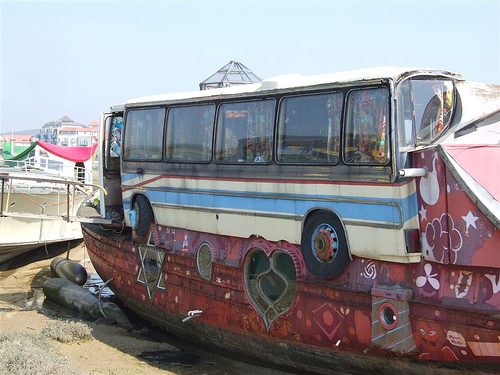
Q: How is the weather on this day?
A: It is clear.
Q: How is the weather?
A: It is clear.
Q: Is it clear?
A: Yes, it is clear.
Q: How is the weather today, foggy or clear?
A: It is clear.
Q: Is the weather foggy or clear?
A: It is clear.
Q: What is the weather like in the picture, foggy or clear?
A: It is clear.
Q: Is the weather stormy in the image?
A: No, it is clear.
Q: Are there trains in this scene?
A: No, there are no trains.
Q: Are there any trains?
A: No, there are no trains.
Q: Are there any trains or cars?
A: No, there are no trains or cars.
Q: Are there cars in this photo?
A: No, there are no cars.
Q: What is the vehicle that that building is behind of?
A: The vehicle is a bus.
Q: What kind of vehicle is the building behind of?
A: The building is behind the bus.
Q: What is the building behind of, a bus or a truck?
A: The building is behind a bus.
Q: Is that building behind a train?
A: No, the building is behind the bus.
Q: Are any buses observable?
A: Yes, there is a bus.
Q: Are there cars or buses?
A: Yes, there is a bus.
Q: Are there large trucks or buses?
A: Yes, there is a large bus.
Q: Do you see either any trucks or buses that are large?
A: Yes, the bus is large.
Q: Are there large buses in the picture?
A: Yes, there is a large bus.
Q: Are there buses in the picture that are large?
A: Yes, there is a bus that is large.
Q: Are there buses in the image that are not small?
A: Yes, there is a large bus.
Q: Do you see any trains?
A: No, there are no trains.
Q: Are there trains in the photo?
A: No, there are no trains.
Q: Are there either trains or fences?
A: No, there are no trains or fences.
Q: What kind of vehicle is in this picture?
A: The vehicle is a bus.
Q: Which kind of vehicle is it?
A: The vehicle is a bus.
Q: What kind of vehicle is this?
A: This is a bus.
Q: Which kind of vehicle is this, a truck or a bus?
A: This is a bus.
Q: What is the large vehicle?
A: The vehicle is a bus.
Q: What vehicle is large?
A: The vehicle is a bus.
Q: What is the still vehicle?
A: The vehicle is a bus.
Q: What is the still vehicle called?
A: The vehicle is a bus.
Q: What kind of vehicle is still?
A: The vehicle is a bus.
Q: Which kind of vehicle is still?
A: The vehicle is a bus.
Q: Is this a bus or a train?
A: This is a bus.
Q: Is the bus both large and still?
A: Yes, the bus is large and still.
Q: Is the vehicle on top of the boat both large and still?
A: Yes, the bus is large and still.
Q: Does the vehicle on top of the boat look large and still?
A: Yes, the bus is large and still.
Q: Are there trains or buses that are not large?
A: No, there is a bus but it is large.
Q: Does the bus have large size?
A: Yes, the bus is large.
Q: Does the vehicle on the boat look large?
A: Yes, the bus is large.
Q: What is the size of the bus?
A: The bus is large.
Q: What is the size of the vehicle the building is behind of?
A: The bus is large.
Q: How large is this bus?
A: The bus is large.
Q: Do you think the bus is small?
A: No, the bus is large.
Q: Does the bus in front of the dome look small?
A: No, the bus is large.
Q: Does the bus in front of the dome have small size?
A: No, the bus is large.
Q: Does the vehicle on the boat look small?
A: No, the bus is large.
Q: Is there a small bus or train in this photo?
A: No, there is a bus but it is large.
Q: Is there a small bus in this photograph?
A: No, there is a bus but it is large.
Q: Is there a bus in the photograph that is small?
A: No, there is a bus but it is large.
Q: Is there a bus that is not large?
A: No, there is a bus but it is large.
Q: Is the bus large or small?
A: The bus is large.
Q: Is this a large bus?
A: Yes, this is a large bus.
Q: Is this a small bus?
A: No, this is a large bus.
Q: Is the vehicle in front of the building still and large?
A: Yes, the bus is still and large.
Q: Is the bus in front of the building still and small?
A: No, the bus is still but large.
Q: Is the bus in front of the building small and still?
A: No, the bus is still but large.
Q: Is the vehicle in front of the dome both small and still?
A: No, the bus is still but large.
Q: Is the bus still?
A: Yes, the bus is still.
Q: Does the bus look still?
A: Yes, the bus is still.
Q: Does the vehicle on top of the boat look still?
A: Yes, the bus is still.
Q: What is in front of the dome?
A: The bus is in front of the dome.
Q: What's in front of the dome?
A: The bus is in front of the dome.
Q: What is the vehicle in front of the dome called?
A: The vehicle is a bus.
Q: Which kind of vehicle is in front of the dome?
A: The vehicle is a bus.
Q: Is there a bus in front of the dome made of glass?
A: Yes, there is a bus in front of the dome.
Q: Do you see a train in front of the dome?
A: No, there is a bus in front of the dome.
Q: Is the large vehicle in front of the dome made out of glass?
A: Yes, the bus is in front of the dome.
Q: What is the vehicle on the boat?
A: The vehicle is a bus.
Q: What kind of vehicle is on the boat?
A: The vehicle is a bus.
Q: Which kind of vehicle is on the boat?
A: The vehicle is a bus.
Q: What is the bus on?
A: The bus is on the boat.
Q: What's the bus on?
A: The bus is on the boat.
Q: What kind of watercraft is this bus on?
A: The bus is on the boat.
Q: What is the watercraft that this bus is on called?
A: The watercraft is a boat.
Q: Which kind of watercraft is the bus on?
A: The bus is on the boat.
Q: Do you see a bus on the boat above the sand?
A: Yes, there is a bus on the boat.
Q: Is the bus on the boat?
A: Yes, the bus is on the boat.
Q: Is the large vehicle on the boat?
A: Yes, the bus is on the boat.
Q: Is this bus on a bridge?
A: No, the bus is on the boat.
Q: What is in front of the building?
A: The bus is in front of the building.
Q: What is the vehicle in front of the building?
A: The vehicle is a bus.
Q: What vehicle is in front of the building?
A: The vehicle is a bus.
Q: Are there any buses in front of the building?
A: Yes, there is a bus in front of the building.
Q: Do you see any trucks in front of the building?
A: No, there is a bus in front of the building.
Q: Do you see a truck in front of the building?
A: No, there is a bus in front of the building.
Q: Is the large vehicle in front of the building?
A: Yes, the bus is in front of the building.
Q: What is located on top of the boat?
A: The bus is on top of the boat.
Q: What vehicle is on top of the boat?
A: The vehicle is a bus.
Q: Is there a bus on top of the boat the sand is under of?
A: Yes, there is a bus on top of the boat.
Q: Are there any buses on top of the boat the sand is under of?
A: Yes, there is a bus on top of the boat.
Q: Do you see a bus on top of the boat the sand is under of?
A: Yes, there is a bus on top of the boat.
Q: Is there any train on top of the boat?
A: No, there is a bus on top of the boat.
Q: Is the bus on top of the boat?
A: Yes, the bus is on top of the boat.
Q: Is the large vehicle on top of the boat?
A: Yes, the bus is on top of the boat.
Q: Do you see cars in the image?
A: No, there are no cars.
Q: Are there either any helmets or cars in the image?
A: No, there are no cars or helmets.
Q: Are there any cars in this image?
A: No, there are no cars.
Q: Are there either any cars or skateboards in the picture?
A: No, there are no cars or skateboards.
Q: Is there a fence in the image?
A: No, there are no fences.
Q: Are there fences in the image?
A: No, there are no fences.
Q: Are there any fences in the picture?
A: No, there are no fences.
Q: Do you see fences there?
A: No, there are no fences.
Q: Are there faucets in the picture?
A: No, there are no faucets.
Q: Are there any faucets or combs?
A: No, there are no faucets or combs.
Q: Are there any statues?
A: No, there are no statues.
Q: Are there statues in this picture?
A: No, there are no statues.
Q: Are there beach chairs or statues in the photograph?
A: No, there are no statues or beach chairs.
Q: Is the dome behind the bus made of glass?
A: Yes, the dome is made of glass.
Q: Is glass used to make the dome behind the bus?
A: Yes, the dome is made of glass.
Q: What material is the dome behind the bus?
A: The dome is made of glass.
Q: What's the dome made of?
A: The dome is made of glass.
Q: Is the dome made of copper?
A: No, the dome is made of glass.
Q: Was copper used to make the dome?
A: No, the dome is made of glass.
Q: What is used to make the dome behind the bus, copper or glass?
A: The dome is made of glass.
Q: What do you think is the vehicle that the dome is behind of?
A: The vehicle is a bus.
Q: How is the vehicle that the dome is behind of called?
A: The vehicle is a bus.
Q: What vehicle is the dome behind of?
A: The dome is behind the bus.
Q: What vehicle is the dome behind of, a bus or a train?
A: The dome is behind a bus.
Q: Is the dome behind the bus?
A: Yes, the dome is behind the bus.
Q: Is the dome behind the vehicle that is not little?
A: Yes, the dome is behind the bus.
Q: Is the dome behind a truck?
A: No, the dome is behind the bus.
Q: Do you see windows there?
A: Yes, there is a window.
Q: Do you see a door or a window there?
A: Yes, there is a window.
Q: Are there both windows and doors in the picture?
A: Yes, there are both a window and a door.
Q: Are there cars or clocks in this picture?
A: No, there are no cars or clocks.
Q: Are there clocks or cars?
A: No, there are no cars or clocks.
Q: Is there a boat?
A: Yes, there is a boat.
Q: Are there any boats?
A: Yes, there is a boat.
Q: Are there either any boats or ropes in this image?
A: Yes, there is a boat.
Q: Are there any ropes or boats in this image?
A: Yes, there is a boat.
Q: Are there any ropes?
A: No, there are no ropes.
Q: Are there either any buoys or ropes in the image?
A: No, there are no ropes or buoys.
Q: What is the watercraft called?
A: The watercraft is a boat.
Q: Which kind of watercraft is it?
A: The watercraft is a boat.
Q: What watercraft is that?
A: This is a boat.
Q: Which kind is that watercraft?
A: This is a boat.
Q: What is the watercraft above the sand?
A: The watercraft is a boat.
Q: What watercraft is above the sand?
A: The watercraft is a boat.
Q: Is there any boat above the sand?
A: Yes, there is a boat above the sand.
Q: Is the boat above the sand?
A: Yes, the boat is above the sand.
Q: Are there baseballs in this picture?
A: No, there are no baseballs.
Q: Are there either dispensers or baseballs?
A: No, there are no baseballs or dispensers.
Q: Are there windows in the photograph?
A: Yes, there is a window.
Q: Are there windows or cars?
A: Yes, there is a window.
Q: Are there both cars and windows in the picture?
A: No, there is a window but no cars.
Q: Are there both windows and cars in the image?
A: No, there is a window but no cars.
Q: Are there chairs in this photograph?
A: No, there are no chairs.